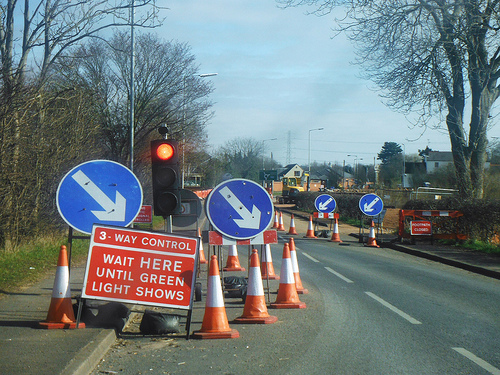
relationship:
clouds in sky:
[307, 92, 422, 150] [4, 5, 498, 168]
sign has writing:
[85, 229, 204, 317] [96, 249, 187, 307]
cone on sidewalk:
[41, 242, 88, 330] [2, 252, 123, 373]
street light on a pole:
[150, 136, 184, 215] [157, 121, 173, 299]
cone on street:
[196, 256, 240, 339] [114, 198, 498, 374]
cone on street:
[239, 251, 279, 327] [114, 198, 498, 374]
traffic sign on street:
[257, 167, 280, 182] [114, 198, 498, 374]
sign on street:
[85, 229, 204, 317] [114, 198, 498, 374]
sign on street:
[205, 178, 282, 241] [114, 198, 498, 374]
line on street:
[297, 238, 433, 340] [114, 198, 498, 374]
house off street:
[258, 165, 322, 202] [114, 198, 498, 374]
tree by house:
[366, 144, 402, 199] [258, 165, 322, 202]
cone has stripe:
[196, 256, 240, 339] [202, 273, 226, 308]